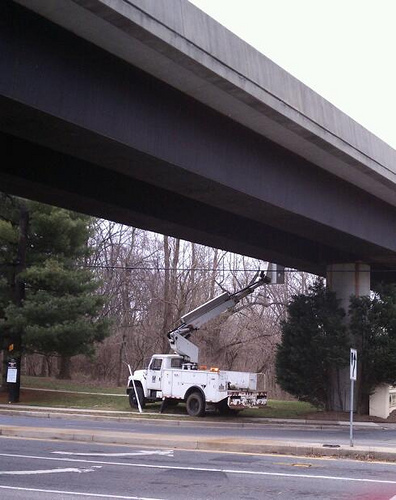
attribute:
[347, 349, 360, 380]
traffic sign —  for traffic,  for direction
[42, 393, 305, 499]
street — paved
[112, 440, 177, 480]
arrows — white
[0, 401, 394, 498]
street — paved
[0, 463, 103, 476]
arrow — white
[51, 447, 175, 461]
arrow — white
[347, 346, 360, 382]
sign — white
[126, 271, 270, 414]
truck — for  work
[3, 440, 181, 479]
arrows — white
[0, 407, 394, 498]
arrows — white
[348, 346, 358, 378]
sign — white and black, rectangular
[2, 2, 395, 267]
overpass —  for traffic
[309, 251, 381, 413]
pillar — light gray, concrete, support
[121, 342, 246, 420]
vehicle — white cherry picker 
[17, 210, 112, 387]
tree — large, evergreen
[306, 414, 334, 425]
sidewalk — gray, concrete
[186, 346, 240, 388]
lights — orange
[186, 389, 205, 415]
tire —  car's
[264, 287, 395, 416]
bush — large, green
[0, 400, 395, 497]
road — light gray, concrete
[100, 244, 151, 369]
trees — bare